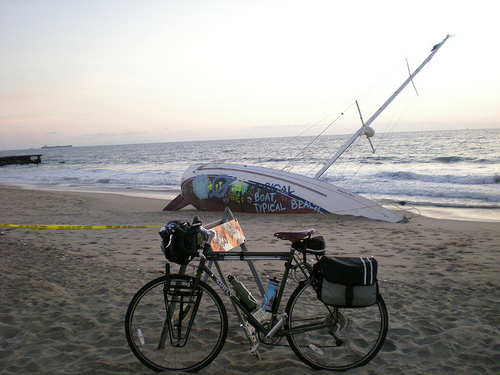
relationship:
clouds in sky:
[0, 0, 500, 145] [8, 9, 481, 144]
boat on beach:
[165, 151, 397, 240] [29, 188, 148, 246]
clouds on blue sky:
[0, 0, 500, 145] [4, 4, 499, 196]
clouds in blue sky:
[0, 0, 500, 145] [26, 24, 218, 103]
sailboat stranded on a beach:
[163, 33, 458, 225] [3, 178, 498, 370]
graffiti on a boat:
[249, 189, 286, 212] [161, 160, 402, 222]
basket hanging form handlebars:
[157, 218, 200, 264] [191, 205, 242, 254]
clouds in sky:
[7, 102, 191, 144] [0, 0, 497, 129]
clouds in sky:
[0, 0, 500, 145] [423, 87, 497, 129]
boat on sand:
[161, 160, 402, 222] [3, 187, 495, 372]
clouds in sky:
[0, 0, 500, 145] [2, 6, 487, 157]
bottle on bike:
[264, 270, 286, 320] [107, 199, 399, 372]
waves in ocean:
[94, 141, 498, 203] [6, 130, 497, 207]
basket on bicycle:
[159, 213, 214, 264] [123, 205, 389, 373]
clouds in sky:
[0, 0, 500, 145] [0, 0, 497, 129]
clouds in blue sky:
[0, 0, 500, 145] [1, 1, 451, 143]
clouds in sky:
[0, 0, 500, 145] [0, 0, 500, 151]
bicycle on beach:
[123, 205, 389, 373] [3, 178, 498, 370]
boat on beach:
[161, 160, 402, 222] [3, 178, 498, 370]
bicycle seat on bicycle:
[269, 225, 321, 250] [123, 203, 389, 373]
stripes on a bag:
[359, 254, 375, 284] [318, 259, 388, 306]